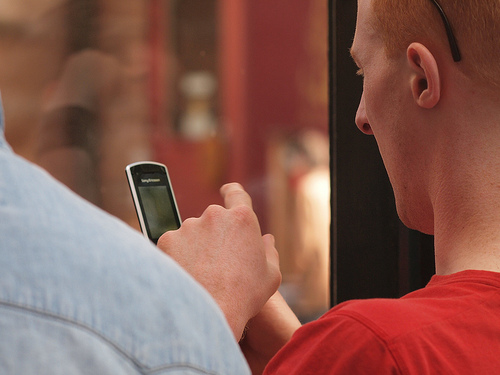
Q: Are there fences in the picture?
A: No, there are no fences.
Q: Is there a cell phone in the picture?
A: Yes, there is a cell phone.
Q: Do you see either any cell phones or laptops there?
A: Yes, there is a cell phone.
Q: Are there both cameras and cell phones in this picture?
A: No, there is a cell phone but no cameras.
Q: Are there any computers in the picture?
A: No, there are no computers.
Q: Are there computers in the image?
A: No, there are no computers.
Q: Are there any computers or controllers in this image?
A: No, there are no computers or controllers.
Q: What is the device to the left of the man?
A: The device is a cell phone.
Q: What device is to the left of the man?
A: The device is a cell phone.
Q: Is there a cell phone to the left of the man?
A: Yes, there is a cell phone to the left of the man.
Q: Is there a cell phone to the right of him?
A: No, the cell phone is to the left of the man.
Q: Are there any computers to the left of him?
A: No, there is a cell phone to the left of the man.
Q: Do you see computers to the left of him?
A: No, there is a cell phone to the left of the man.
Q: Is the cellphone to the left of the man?
A: Yes, the cellphone is to the left of the man.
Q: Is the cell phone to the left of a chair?
A: No, the cell phone is to the left of the man.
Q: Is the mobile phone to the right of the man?
A: No, the mobile phone is to the left of the man.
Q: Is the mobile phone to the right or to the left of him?
A: The mobile phone is to the left of the man.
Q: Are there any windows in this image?
A: Yes, there is a window.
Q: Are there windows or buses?
A: Yes, there is a window.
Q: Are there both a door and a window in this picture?
A: No, there is a window but no doors.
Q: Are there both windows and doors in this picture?
A: No, there is a window but no doors.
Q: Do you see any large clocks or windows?
A: Yes, there is a large window.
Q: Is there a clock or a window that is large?
A: Yes, the window is large.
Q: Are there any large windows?
A: Yes, there is a large window.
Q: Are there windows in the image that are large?
A: Yes, there is a window that is large.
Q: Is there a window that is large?
A: Yes, there is a window that is large.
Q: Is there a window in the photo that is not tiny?
A: Yes, there is a large window.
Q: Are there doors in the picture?
A: No, there are no doors.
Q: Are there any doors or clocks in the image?
A: No, there are no doors or clocks.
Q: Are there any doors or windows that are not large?
A: No, there is a window but it is large.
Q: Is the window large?
A: Yes, the window is large.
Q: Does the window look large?
A: Yes, the window is large.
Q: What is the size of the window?
A: The window is large.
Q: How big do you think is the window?
A: The window is large.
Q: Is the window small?
A: No, the window is large.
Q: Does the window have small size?
A: No, the window is large.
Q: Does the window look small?
A: No, the window is large.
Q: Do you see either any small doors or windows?
A: No, there is a window but it is large.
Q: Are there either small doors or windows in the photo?
A: No, there is a window but it is large.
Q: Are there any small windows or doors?
A: No, there is a window but it is large.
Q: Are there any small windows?
A: No, there is a window but it is large.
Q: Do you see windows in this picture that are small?
A: No, there is a window but it is large.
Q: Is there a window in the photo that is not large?
A: No, there is a window but it is large.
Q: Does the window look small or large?
A: The window is large.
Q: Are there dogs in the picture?
A: No, there are no dogs.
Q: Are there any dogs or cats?
A: No, there are no dogs or cats.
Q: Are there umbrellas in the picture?
A: No, there are no umbrellas.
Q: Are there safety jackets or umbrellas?
A: No, there are no umbrellas or safety jackets.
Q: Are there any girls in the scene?
A: No, there are no girls.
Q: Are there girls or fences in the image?
A: No, there are no girls or fences.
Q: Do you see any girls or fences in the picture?
A: No, there are no girls or fences.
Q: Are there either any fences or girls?
A: No, there are no girls or fences.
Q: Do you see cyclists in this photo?
A: No, there are no cyclists.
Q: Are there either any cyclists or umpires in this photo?
A: No, there are no cyclists or umpires.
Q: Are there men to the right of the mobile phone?
A: Yes, there is a man to the right of the mobile phone.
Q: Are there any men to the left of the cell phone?
A: No, the man is to the right of the cell phone.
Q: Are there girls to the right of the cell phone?
A: No, there is a man to the right of the cell phone.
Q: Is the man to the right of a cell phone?
A: Yes, the man is to the right of a cell phone.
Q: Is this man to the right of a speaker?
A: No, the man is to the right of a cell phone.